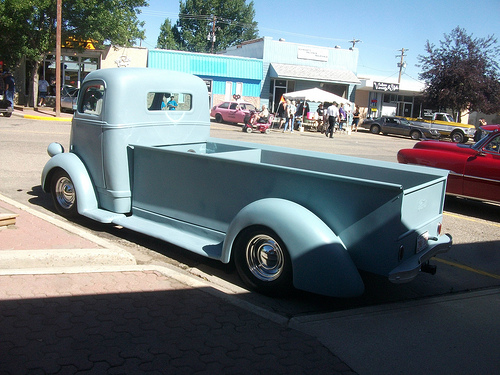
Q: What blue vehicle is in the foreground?
A: A truck.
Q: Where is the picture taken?
A: A parking lot.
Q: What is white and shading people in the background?
A: A tent.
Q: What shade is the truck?
A: Light blue.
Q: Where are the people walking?
A: Towards the canopy.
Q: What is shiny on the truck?
A: The hub caps.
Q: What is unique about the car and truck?
A: They are antiques.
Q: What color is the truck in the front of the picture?
A: Blue.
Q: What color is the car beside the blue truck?
A: Red.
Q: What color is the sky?
A: Blue.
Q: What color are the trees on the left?
A: Green.